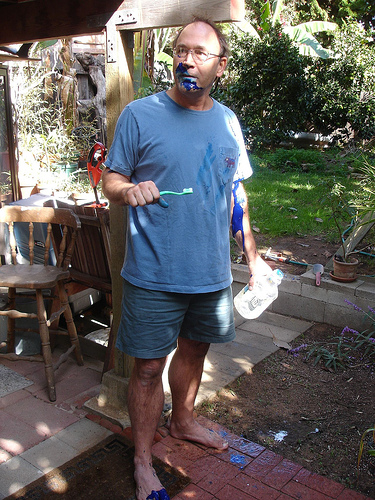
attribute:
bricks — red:
[250, 449, 272, 468]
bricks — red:
[224, 479, 260, 492]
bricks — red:
[281, 470, 320, 488]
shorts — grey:
[113, 274, 236, 364]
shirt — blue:
[65, 69, 278, 309]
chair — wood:
[0, 205, 86, 403]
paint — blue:
[146, 489, 171, 498]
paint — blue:
[230, 451, 246, 468]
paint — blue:
[173, 62, 203, 90]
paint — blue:
[230, 177, 245, 250]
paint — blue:
[218, 430, 228, 436]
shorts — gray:
[73, 274, 239, 367]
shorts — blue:
[115, 276, 233, 360]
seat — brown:
[0, 260, 76, 291]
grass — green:
[244, 150, 373, 251]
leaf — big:
[291, 33, 337, 59]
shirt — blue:
[103, 92, 253, 294]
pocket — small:
[219, 148, 244, 181]